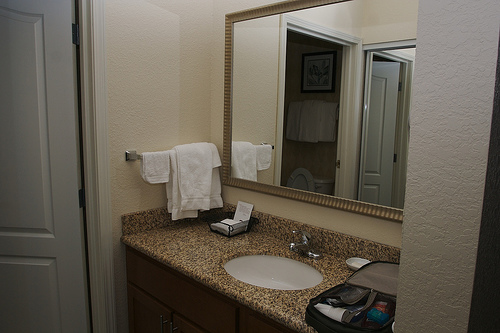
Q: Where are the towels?
A: On the rack.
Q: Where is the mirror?
A: On the wall.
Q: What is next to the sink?
A: A travel kit.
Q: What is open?
A: The door.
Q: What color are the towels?
A: White.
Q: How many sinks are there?
A: One.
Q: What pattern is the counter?
A: Dappled.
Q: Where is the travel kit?
A: On the counter.